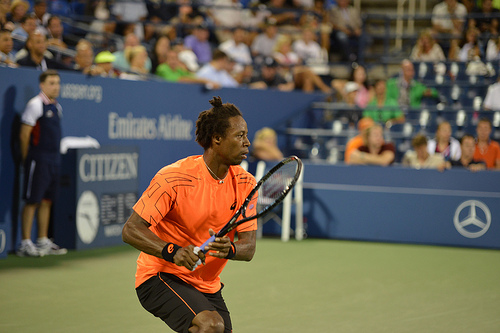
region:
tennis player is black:
[95, 45, 366, 299]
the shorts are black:
[91, 236, 264, 325]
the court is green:
[307, 296, 397, 331]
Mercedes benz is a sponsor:
[421, 162, 494, 234]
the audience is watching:
[336, 107, 496, 185]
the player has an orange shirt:
[102, 99, 369, 274]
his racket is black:
[117, 155, 367, 295]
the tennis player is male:
[136, 126, 325, 273]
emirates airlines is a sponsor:
[90, 99, 286, 215]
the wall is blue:
[369, 202, 419, 245]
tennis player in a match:
[107, 82, 303, 331]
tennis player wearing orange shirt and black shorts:
[121, 85, 252, 330]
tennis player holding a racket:
[125, 87, 304, 329]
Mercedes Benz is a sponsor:
[396, 168, 498, 261]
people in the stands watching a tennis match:
[5, 3, 497, 330]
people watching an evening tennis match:
[3, 1, 453, 330]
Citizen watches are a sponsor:
[66, 145, 156, 253]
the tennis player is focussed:
[95, 75, 343, 331]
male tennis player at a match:
[115, 83, 285, 330]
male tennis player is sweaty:
[154, 77, 259, 331]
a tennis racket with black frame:
[176, 153, 305, 273]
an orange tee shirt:
[129, 153, 259, 295]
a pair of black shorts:
[135, 266, 232, 331]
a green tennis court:
[294, 276, 421, 332]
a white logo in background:
[451, 201, 494, 241]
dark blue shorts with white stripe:
[22, 148, 60, 204]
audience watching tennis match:
[341, 73, 498, 167]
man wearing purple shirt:
[185, 13, 214, 63]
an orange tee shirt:
[471, 138, 499, 168]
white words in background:
[100, 109, 198, 144]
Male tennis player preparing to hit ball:
[117, 97, 257, 332]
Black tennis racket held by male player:
[196, 155, 301, 250]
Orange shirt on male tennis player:
[135, 156, 257, 293]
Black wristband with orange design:
[158, 240, 179, 260]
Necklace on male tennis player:
[203, 160, 230, 186]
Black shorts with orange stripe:
[136, 270, 232, 330]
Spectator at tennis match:
[346, 121, 396, 171]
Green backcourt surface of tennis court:
[0, 239, 498, 329]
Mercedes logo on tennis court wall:
[447, 195, 495, 240]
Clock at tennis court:
[73, 187, 103, 243]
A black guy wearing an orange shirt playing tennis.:
[120, 97, 254, 332]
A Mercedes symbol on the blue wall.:
[449, 200, 491, 237]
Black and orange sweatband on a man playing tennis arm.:
[159, 237, 180, 262]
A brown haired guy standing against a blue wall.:
[15, 69, 70, 257]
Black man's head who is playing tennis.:
[194, 95, 251, 170]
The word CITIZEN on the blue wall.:
[80, 154, 138, 181]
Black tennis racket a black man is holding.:
[188, 149, 303, 270]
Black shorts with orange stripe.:
[132, 266, 233, 331]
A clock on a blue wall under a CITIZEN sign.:
[97, 192, 143, 229]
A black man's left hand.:
[205, 232, 232, 260]